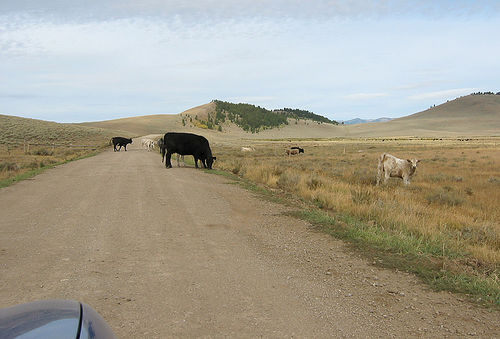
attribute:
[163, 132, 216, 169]
cow — black, grazing, several, large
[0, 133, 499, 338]
road — tan, worn, dirt, gravel, long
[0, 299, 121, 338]
vehicle — blue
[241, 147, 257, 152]
cow — white, large, standing, grazing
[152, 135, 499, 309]
field — grassy, green, wide open, large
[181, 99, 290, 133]
hill — small, large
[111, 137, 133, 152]
cow — black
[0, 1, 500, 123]
sky — blue, clear, sunny, cloudy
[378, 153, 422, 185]
cow — white, brown